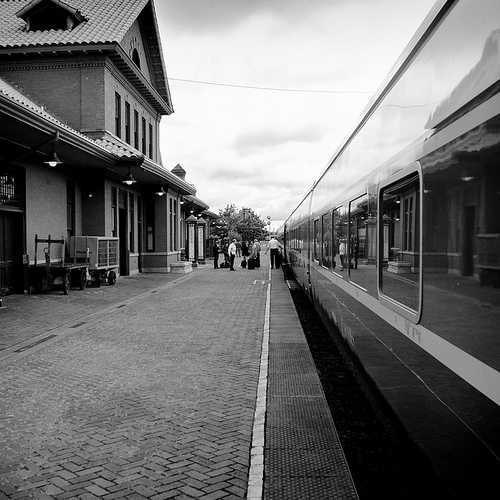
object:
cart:
[47, 235, 120, 295]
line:
[243, 247, 273, 498]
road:
[1, 230, 358, 499]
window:
[167, 196, 178, 251]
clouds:
[167, 0, 412, 211]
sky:
[150, 0, 441, 235]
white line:
[243, 261, 275, 499]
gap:
[281, 265, 449, 499]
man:
[264, 236, 284, 269]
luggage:
[240, 257, 258, 269]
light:
[155, 189, 165, 198]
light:
[121, 173, 139, 185]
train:
[274, 18, 498, 497]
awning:
[1, 82, 220, 221]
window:
[127, 195, 136, 254]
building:
[0, 1, 217, 306]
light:
[42, 155, 64, 168]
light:
[197, 212, 203, 218]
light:
[179, 200, 185, 205]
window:
[141, 196, 160, 254]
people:
[212, 236, 283, 269]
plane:
[160, 287, 245, 441]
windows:
[105, 89, 162, 163]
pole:
[185, 209, 198, 267]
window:
[373, 175, 428, 314]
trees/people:
[212, 205, 262, 271]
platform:
[4, 222, 372, 500]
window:
[321, 211, 331, 268]